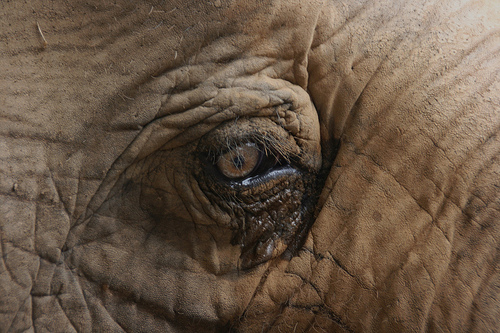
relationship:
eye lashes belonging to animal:
[220, 136, 298, 162] [2, 0, 499, 333]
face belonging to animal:
[1, 1, 484, 331] [2, 0, 499, 333]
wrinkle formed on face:
[159, 83, 200, 92] [1, 1, 484, 331]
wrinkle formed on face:
[215, 80, 278, 91] [1, 1, 484, 331]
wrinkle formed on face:
[189, 50, 300, 61] [1, 1, 484, 331]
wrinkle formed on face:
[154, 113, 229, 153] [1, 1, 484, 331]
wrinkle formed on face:
[304, 0, 324, 89] [1, 1, 484, 331]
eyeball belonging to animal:
[200, 116, 285, 200] [2, 0, 499, 333]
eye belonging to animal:
[199, 135, 299, 187] [2, 0, 484, 328]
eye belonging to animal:
[199, 135, 299, 187] [2, 0, 499, 333]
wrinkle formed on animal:
[76, 261, 241, 331] [2, 0, 499, 333]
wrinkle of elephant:
[375, 118, 457, 242] [11, 3, 483, 275]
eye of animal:
[208, 139, 287, 189] [2, 0, 499, 333]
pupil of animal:
[228, 152, 252, 170] [2, 0, 499, 333]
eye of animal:
[199, 135, 299, 187] [2, 0, 499, 333]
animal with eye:
[2, 0, 499, 333] [204, 130, 307, 200]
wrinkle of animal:
[329, 78, 384, 176] [2, 0, 499, 333]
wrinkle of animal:
[309, 250, 352, 290] [2, 0, 499, 333]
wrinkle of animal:
[45, 215, 125, 297] [2, 0, 499, 333]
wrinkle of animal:
[401, 236, 478, 309] [2, 0, 499, 333]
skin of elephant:
[4, 5, 497, 331] [10, 4, 483, 307]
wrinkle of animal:
[64, 136, 118, 237] [2, 0, 499, 333]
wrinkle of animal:
[120, 76, 209, 145] [2, 0, 499, 333]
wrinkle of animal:
[126, 287, 187, 327] [2, 0, 499, 333]